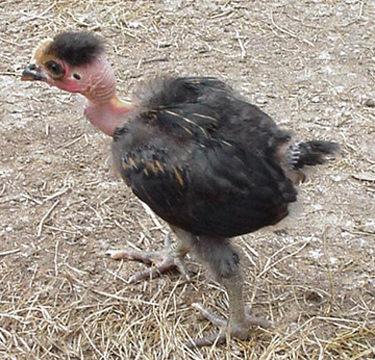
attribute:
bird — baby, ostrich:
[21, 28, 340, 350]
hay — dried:
[2, 226, 372, 357]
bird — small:
[15, 9, 346, 357]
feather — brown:
[140, 156, 189, 189]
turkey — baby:
[22, 41, 295, 296]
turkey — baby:
[20, 25, 350, 343]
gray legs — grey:
[143, 246, 241, 327]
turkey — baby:
[35, 59, 298, 315]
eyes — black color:
[32, 49, 73, 77]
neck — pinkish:
[80, 73, 134, 142]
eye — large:
[42, 60, 69, 82]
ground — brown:
[228, 15, 360, 77]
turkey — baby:
[27, 31, 334, 263]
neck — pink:
[82, 87, 135, 137]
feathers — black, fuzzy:
[43, 28, 110, 68]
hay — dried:
[3, 3, 373, 359]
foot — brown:
[189, 300, 268, 348]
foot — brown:
[104, 247, 198, 292]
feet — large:
[118, 243, 274, 344]